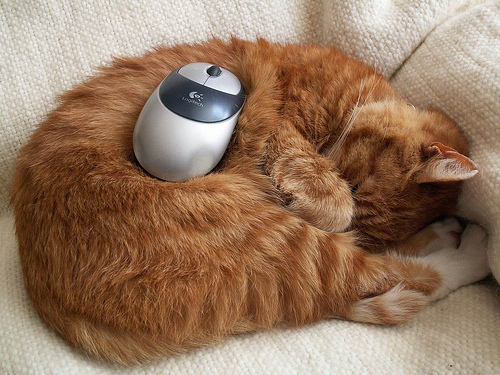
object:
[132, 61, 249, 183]
mouse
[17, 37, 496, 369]
cat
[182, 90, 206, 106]
logo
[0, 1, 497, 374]
couch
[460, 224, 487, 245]
toes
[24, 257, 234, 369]
tail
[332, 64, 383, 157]
whiskers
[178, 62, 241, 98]
buttons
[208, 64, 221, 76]
scroll-wheel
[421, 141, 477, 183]
ears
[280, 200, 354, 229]
paw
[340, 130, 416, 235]
face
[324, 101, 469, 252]
head